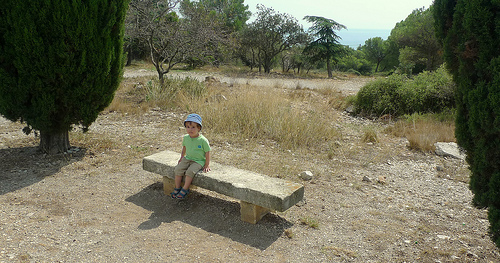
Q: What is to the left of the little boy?
A: Green tree.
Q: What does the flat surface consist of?
A: The ground is dirt.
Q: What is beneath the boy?
A: Bench made of stone.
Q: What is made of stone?
A: Off white bench.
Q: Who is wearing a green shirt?
A: Someone sitting on the bench.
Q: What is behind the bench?
A: Tan dry grass and rocks.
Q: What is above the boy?
A: Tree without leaves.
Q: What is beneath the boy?
A: Shadow of bench and boy.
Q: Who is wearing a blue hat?
A: The boy.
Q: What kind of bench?
A: Wooden bench.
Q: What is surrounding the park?
A: Trees.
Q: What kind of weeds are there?
A: Dead weeds.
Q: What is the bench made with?
A: Stone.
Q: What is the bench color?
A: Tan.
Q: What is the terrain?
A: Rocky.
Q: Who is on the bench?
A: The boy.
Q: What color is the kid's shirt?
A: Green.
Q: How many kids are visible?
A: 1.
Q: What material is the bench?
A: Stone.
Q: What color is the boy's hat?
A: Blue.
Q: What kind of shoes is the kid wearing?
A: Sandals.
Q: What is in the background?
A: Trees.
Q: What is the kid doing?
A: Sitting.